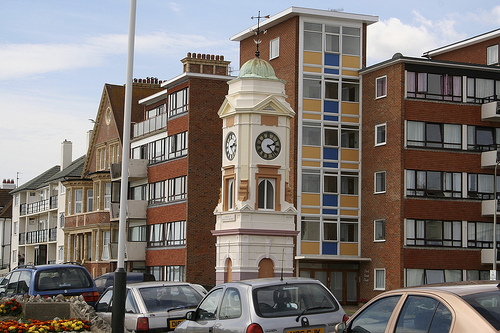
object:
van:
[0, 263, 99, 308]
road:
[1, 297, 500, 332]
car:
[170, 275, 351, 332]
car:
[90, 280, 208, 332]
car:
[332, 281, 499, 332]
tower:
[211, 10, 300, 284]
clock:
[255, 130, 282, 161]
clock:
[224, 131, 238, 161]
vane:
[249, 8, 271, 58]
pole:
[114, 0, 137, 270]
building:
[59, 7, 500, 302]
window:
[374, 74, 387, 100]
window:
[374, 122, 387, 147]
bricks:
[213, 94, 215, 96]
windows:
[404, 120, 426, 141]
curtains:
[407, 70, 410, 97]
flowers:
[66, 325, 76, 331]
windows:
[340, 222, 359, 243]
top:
[233, 56, 277, 79]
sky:
[0, 1, 196, 89]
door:
[192, 288, 222, 331]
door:
[250, 307, 348, 329]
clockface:
[256, 131, 280, 159]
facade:
[300, 20, 363, 258]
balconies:
[109, 159, 148, 182]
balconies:
[481, 97, 499, 122]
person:
[18, 253, 24, 265]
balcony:
[25, 260, 57, 267]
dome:
[238, 58, 279, 80]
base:
[111, 269, 128, 332]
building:
[10, 139, 86, 274]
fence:
[17, 228, 57, 246]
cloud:
[2, 31, 68, 70]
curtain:
[305, 23, 321, 50]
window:
[302, 30, 324, 52]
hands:
[267, 145, 274, 152]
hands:
[230, 147, 235, 156]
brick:
[292, 42, 296, 43]